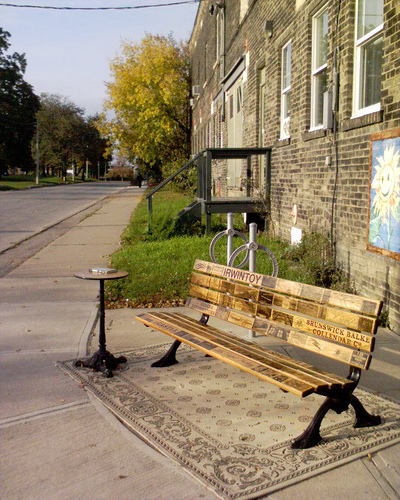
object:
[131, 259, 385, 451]
bench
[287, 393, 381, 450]
legs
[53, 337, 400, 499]
rug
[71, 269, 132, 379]
table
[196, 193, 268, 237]
platform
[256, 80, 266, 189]
door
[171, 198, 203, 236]
stairs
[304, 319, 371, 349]
words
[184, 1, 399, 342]
wall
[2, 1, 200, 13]
wire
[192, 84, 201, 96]
air conditioner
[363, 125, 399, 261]
painting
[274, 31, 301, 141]
window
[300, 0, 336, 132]
window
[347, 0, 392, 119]
window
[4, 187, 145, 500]
sidewalk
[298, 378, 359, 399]
edge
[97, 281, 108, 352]
stand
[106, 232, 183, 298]
grass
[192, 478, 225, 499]
edge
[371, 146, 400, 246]
sunflower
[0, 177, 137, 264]
road